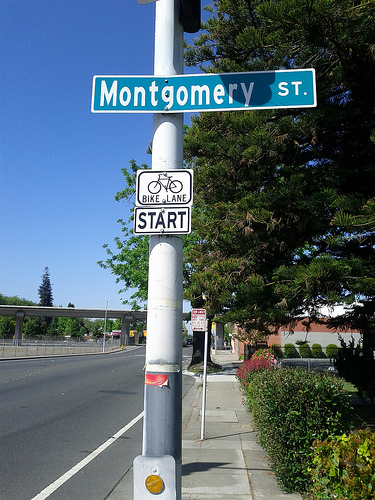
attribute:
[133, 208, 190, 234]
traffic sign — white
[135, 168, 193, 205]
sign — traffic, black, white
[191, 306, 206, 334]
sign — white 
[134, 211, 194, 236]
sign — black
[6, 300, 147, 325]
stone bridge — stone 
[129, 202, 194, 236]
sign — black, white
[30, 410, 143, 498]
line — white 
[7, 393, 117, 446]
street — paved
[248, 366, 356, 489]
hedge bush — green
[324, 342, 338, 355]
hedge bush — green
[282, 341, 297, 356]
hedge bush — green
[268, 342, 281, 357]
hedge bush — green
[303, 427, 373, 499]
hedge bush — green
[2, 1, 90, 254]
sky — blue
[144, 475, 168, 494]
light — yellow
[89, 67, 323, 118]
street sign — white 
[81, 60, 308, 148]
sticker — red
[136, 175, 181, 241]
sign — no parking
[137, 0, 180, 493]
pole — metal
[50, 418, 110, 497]
lane — marked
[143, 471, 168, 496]
dot — yellow 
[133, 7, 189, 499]
street pole — tall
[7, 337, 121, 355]
fence — metal 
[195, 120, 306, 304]
green leaves — green 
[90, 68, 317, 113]
sign — green, white, street